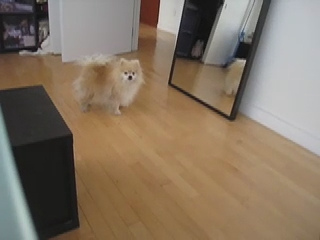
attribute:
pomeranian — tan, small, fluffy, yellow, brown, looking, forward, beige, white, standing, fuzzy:
[73, 54, 146, 116]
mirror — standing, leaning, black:
[168, 1, 270, 119]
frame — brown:
[168, 1, 270, 120]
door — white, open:
[58, 1, 136, 64]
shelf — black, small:
[2, 0, 52, 53]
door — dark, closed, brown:
[140, 1, 161, 25]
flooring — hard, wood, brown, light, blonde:
[1, 22, 320, 240]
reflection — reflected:
[221, 58, 249, 97]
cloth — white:
[20, 35, 63, 57]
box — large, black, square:
[2, 85, 80, 240]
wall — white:
[174, 0, 319, 158]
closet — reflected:
[174, 0, 255, 68]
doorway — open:
[139, 0, 183, 70]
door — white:
[200, 1, 248, 66]